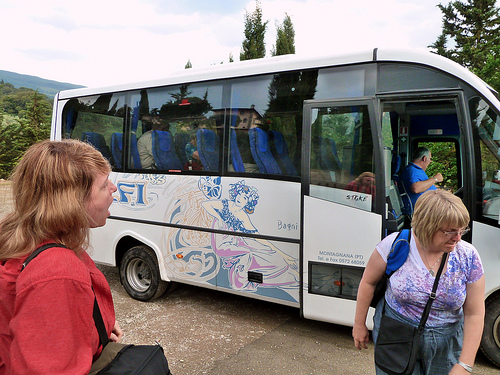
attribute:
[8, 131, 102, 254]
hair — light brown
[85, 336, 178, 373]
bag — black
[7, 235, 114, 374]
shirt — red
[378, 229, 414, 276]
strap — blue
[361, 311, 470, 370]
pants — grey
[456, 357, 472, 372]
band — silver, white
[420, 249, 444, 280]
necklace — silver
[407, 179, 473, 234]
hair — short, blonde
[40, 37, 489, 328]
bus — white, present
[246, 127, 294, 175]
seats — blue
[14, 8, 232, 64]
sky — cloudy, blue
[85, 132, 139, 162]
seats — blue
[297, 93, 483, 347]
door — open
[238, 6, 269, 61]
tree — tall, green